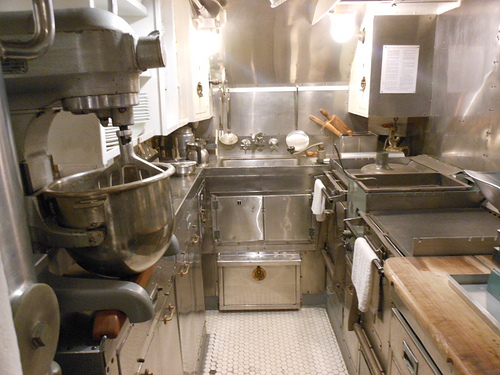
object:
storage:
[211, 191, 323, 249]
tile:
[209, 332, 215, 337]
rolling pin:
[308, 113, 343, 138]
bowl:
[40, 161, 181, 282]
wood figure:
[465, 339, 500, 375]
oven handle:
[342, 216, 371, 241]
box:
[216, 248, 303, 312]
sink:
[350, 164, 470, 193]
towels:
[302, 178, 327, 221]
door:
[210, 177, 321, 253]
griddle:
[361, 185, 500, 258]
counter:
[0, 132, 498, 375]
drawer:
[390, 304, 445, 374]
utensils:
[218, 84, 225, 139]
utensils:
[219, 86, 240, 146]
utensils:
[286, 84, 309, 152]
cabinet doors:
[211, 191, 315, 253]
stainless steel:
[324, 178, 338, 303]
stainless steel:
[219, 195, 314, 237]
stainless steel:
[235, 30, 352, 81]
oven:
[318, 169, 350, 274]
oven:
[334, 219, 391, 360]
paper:
[379, 45, 420, 94]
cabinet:
[346, 10, 436, 122]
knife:
[308, 109, 350, 138]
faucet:
[250, 131, 264, 147]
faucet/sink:
[237, 132, 297, 152]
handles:
[310, 107, 348, 137]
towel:
[350, 235, 382, 315]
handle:
[342, 217, 384, 273]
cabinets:
[106, 0, 214, 147]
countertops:
[171, 169, 200, 218]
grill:
[351, 206, 498, 254]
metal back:
[423, 0, 498, 173]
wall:
[213, 0, 500, 183]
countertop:
[386, 254, 498, 369]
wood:
[406, 267, 444, 293]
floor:
[205, 306, 348, 375]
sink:
[222, 158, 298, 168]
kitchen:
[1, 0, 498, 375]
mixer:
[0, 0, 172, 275]